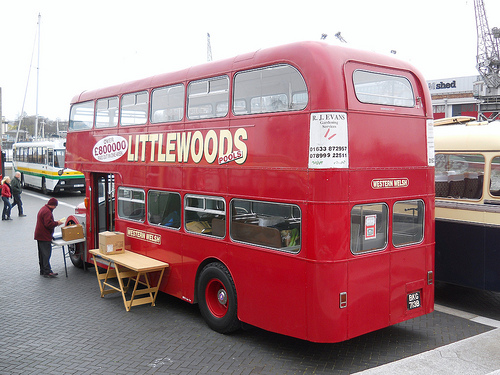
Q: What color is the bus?
A: Red.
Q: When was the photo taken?
A: Daytime.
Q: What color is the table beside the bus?
A: Tan.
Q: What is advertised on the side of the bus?
A: Littlewoods Pools.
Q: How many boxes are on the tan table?
A: One.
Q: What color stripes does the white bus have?
A: Yellow and green.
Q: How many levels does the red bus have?
A: Two.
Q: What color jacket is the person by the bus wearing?
A: Red.